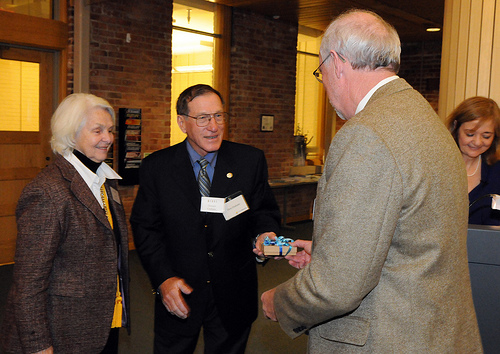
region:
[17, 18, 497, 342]
people at a gathering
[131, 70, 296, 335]
man receiving wrapped gift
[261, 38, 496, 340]
man giving wrapped gift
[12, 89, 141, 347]
woman next to man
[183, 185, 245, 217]
tags on man's suit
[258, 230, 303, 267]
wrapped gift being given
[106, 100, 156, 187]
pamphlets on the wall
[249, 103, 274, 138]
plaque on the wall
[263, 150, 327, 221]
table against the wall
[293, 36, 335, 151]
window in the back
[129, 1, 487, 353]
the gift exchange between the men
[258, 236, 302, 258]
the gift in the mens hands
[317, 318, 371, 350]
the pocket on the jacket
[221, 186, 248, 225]
the tag on the mans shirt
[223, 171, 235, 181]
the gold button on the jacket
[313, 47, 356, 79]
the glasses on the mans ear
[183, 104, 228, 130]
the glasses on the mans face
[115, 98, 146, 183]
the magazine holder on the wall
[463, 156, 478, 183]
the pearl necklace on the women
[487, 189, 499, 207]
the white tag clipped to the womens shirt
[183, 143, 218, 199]
blue collared shirt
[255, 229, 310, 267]
the men are holding a small box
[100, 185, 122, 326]
yellow tassels on the woman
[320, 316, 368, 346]
suit pocket cover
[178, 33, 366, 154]
both men are wearing glasses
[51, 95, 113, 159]
the older woman has gray hair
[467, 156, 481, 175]
a necklace of pearls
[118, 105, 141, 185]
magazine holder on the wall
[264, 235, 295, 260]
blue ribbon the box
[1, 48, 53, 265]
wooden door with a window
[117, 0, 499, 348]
people exchanging a gift box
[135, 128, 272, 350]
man wearing black suit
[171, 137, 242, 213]
man wearing blue shirt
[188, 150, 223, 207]
man wearing striped tie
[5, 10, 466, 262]
brick wall in background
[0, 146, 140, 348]
woman wearing brown jacket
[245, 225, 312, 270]
man holding tan box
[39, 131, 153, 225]
woman wearing white shirt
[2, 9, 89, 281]
brown door in background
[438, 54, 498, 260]
woman smiling in background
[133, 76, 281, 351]
a man wearing a black coat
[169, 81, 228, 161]
a man wearing glasses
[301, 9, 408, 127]
a man wearing glasses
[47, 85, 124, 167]
a woman with white hair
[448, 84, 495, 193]
a woman with brown hair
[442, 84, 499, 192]
a woman wearing a pearl necklace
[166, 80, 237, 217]
a man wearing a tie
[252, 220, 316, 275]
two hands holding a wrapped gift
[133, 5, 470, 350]
two men exchanging a gift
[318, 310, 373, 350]
a pocket on a suit